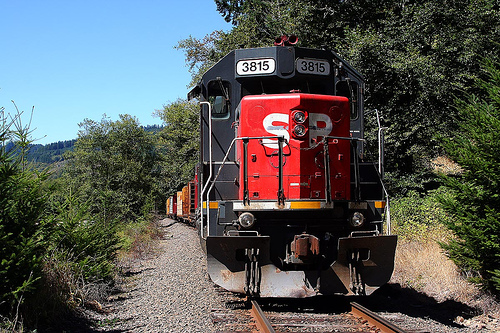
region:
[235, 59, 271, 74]
The number 3815 on the left.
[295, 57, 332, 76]
The number 3815 on the right.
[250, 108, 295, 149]
The letter S on the left of the train.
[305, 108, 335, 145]
The letter P on the right.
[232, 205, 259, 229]
The left headlight of the train.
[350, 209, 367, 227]
The right headlight on the train.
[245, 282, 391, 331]
The tracks in front of the train.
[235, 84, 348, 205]
The red structure on the front of the train.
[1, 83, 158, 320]
The trees on the left.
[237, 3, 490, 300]
The trees on the right.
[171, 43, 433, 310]
A large train engine.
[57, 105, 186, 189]
Trees behind the train engine.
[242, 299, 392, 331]
A rusty railroad track.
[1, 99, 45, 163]
A piece of brush extending toward the sky.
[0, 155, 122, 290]
Brush on the side of the hill.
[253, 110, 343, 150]
Two large, white Letters: "S" and "P."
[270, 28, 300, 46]
Small horns atop the train.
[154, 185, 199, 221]
A line of additional train cars.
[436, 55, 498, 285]
A mid-size tree to the left of the train.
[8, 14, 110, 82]
A beautiful blue sky overlooking the scene.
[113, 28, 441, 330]
A train traveling through the countryside.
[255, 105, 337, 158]
The letters S P in white writing.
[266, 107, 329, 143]
Two lights between the letters S and P.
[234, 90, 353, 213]
Part of the engine is red.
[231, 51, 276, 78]
The number 3815 on left top of the train.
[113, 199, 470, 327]
Gravel on the railroad bed.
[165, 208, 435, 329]
Crossties under a railroad track.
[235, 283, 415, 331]
Rails of the railroad track.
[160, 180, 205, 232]
Railroad cars on the train.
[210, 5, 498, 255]
Green trees on the left side of the train.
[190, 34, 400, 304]
a black and red train engine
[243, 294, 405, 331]
a set of train tracks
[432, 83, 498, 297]
a large green tree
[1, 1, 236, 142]
a deep blue clear sky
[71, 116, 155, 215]
a large tree in distanc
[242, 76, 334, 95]
a train engine windshield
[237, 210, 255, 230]
a train engine headlight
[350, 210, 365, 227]
a train engine headlight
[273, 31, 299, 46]
a train engine horn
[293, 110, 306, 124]
a train engine headlight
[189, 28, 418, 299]
A red train traveling down tracks.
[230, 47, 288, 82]
Numbers written on a train.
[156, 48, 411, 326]
A red and black train on tracks.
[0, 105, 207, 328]
A hillside covered in green grass.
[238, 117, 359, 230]
A metal railing on the front of a train.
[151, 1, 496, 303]
Lush green trees.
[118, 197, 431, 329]
Train tracks on a hillside.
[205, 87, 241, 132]
A window on the front of a train.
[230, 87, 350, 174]
Numbers written on a train.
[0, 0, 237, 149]
A clear blue sky.